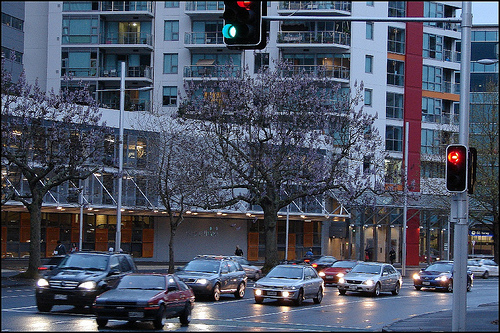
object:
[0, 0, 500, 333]
intersection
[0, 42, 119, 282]
tree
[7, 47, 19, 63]
purple flowers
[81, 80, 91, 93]
purple flowers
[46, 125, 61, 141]
purple flowers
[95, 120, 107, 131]
purple flowers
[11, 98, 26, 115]
purple flowers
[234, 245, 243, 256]
man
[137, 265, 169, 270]
sidewalk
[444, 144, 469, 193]
light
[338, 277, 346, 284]
headlights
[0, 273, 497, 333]
surface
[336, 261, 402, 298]
car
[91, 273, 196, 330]
car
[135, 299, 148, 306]
light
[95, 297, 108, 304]
light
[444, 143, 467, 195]
signal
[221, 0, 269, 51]
light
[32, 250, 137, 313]
suv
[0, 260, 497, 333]
street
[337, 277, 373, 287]
lights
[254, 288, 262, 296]
headlights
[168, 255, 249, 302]
car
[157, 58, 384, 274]
tree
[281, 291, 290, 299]
headlight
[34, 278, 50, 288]
headlights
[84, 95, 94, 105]
flower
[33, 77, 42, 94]
flower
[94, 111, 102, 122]
flower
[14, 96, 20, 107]
flower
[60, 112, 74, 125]
flower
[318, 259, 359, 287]
car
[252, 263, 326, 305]
car